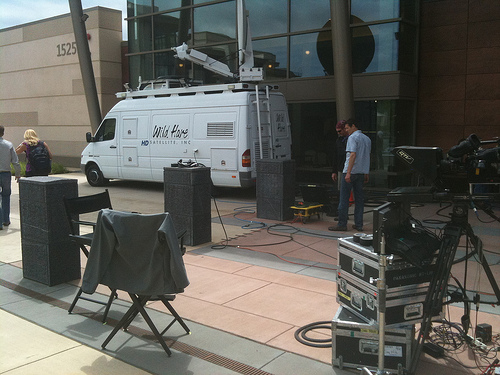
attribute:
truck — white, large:
[80, 73, 304, 190]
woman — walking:
[7, 125, 53, 175]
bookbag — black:
[21, 143, 52, 178]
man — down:
[341, 118, 372, 237]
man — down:
[328, 116, 345, 229]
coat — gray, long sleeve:
[76, 192, 188, 319]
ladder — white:
[246, 76, 277, 159]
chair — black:
[62, 184, 121, 336]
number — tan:
[50, 38, 81, 60]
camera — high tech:
[383, 129, 495, 214]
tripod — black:
[408, 194, 498, 370]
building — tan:
[1, 9, 147, 185]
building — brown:
[112, 0, 498, 197]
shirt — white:
[0, 137, 18, 177]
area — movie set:
[5, 3, 486, 322]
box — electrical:
[160, 154, 216, 250]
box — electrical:
[250, 155, 299, 227]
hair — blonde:
[24, 127, 39, 151]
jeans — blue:
[326, 174, 370, 236]